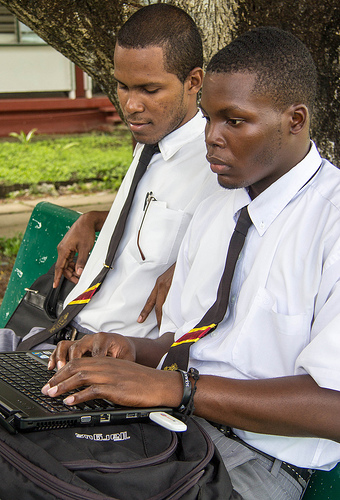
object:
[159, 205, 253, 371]
neck tie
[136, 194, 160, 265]
reading glasses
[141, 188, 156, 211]
pen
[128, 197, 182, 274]
pocket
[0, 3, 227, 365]
students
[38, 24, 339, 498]
student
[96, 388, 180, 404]
edge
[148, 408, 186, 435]
usb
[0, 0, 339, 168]
trunks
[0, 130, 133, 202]
grass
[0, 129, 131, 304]
ground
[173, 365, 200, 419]
wrist band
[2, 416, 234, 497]
laptop bag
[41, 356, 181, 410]
hand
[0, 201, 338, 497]
bench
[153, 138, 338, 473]
shirt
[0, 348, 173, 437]
laptop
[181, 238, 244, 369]
edge